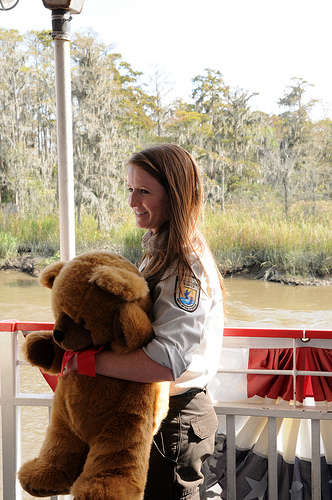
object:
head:
[39, 251, 155, 352]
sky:
[1, 0, 330, 122]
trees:
[277, 105, 305, 220]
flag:
[201, 347, 330, 497]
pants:
[151, 400, 216, 498]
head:
[126, 140, 202, 233]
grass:
[270, 213, 277, 222]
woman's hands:
[62, 345, 87, 378]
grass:
[231, 234, 237, 268]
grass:
[237, 230, 241, 257]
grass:
[250, 231, 255, 252]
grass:
[268, 234, 273, 268]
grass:
[304, 230, 309, 266]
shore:
[224, 267, 321, 284]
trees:
[73, 30, 120, 222]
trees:
[192, 63, 251, 186]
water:
[20, 406, 38, 446]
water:
[315, 310, 330, 330]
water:
[18, 375, 36, 392]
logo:
[174, 265, 201, 314]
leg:
[70, 429, 151, 498]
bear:
[18, 244, 171, 499]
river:
[301, 282, 332, 330]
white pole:
[51, 36, 76, 255]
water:
[228, 298, 244, 319]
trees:
[166, 104, 210, 154]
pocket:
[186, 412, 217, 454]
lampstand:
[55, 38, 75, 257]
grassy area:
[0, 201, 332, 272]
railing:
[213, 314, 332, 500]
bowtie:
[57, 344, 102, 379]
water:
[0, 282, 16, 304]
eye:
[128, 188, 132, 193]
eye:
[140, 188, 149, 194]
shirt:
[134, 225, 224, 395]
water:
[4, 272, 14, 282]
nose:
[128, 196, 141, 206]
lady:
[60, 143, 227, 499]